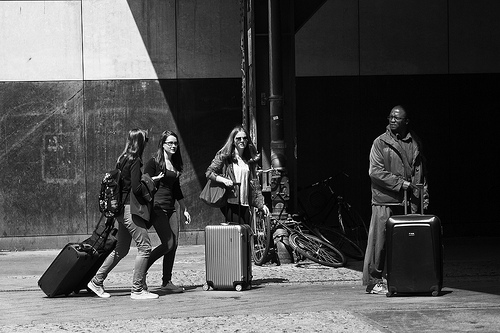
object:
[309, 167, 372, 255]
bike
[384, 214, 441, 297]
luggage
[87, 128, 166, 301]
woman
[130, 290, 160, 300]
shoe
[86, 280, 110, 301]
shoe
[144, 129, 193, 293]
person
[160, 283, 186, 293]
shoe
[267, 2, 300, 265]
pole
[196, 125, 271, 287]
person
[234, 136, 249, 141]
sunglasses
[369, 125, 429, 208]
jacket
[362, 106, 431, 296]
person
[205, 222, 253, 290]
luggage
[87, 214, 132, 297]
leg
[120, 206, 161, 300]
leg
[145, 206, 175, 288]
leg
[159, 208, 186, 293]
leg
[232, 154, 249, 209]
shirt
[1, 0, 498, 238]
wall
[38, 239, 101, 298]
luggage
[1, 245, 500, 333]
ground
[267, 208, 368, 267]
bicycle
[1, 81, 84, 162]
crack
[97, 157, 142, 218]
bag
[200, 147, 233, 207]
bag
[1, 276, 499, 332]
sidewalk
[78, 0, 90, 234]
line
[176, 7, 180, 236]
line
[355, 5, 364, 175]
line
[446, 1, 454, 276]
line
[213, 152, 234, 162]
shoulder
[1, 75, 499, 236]
black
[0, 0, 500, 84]
white